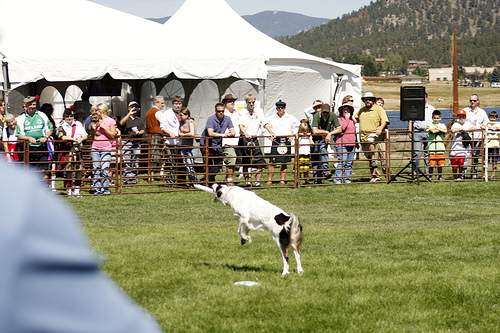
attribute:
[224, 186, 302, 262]
dog — white, jumping, black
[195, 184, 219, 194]
frisbee — white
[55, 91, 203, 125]
people — watching, background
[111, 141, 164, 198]
fence — brown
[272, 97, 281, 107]
hat — red, white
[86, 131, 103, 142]
shirt — green, yellow, pink, tan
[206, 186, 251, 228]
goat — spotted, charging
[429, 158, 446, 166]
shorts — orange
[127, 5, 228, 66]
tent — white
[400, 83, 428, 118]
speaker — black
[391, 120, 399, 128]
water — small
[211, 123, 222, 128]
jacket — blue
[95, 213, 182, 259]
grass — green